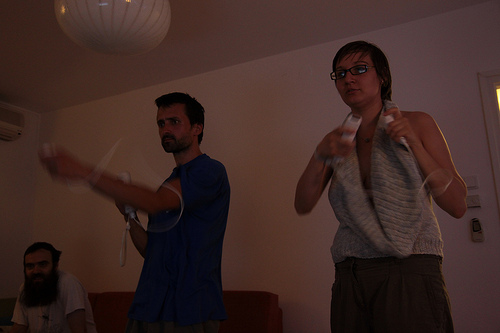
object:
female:
[289, 37, 469, 332]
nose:
[343, 72, 357, 85]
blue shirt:
[127, 155, 232, 319]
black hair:
[153, 91, 207, 145]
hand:
[384, 111, 417, 144]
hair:
[332, 40, 392, 101]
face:
[333, 52, 378, 105]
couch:
[3, 291, 284, 332]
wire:
[432, 176, 455, 199]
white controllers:
[382, 115, 407, 148]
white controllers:
[339, 114, 364, 147]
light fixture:
[52, 4, 173, 61]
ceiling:
[0, 0, 494, 117]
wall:
[39, 0, 499, 327]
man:
[9, 241, 93, 332]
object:
[52, 1, 172, 54]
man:
[36, 91, 238, 329]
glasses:
[328, 64, 382, 81]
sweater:
[328, 100, 445, 260]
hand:
[45, 147, 86, 182]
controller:
[35, 141, 60, 160]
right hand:
[315, 129, 354, 158]